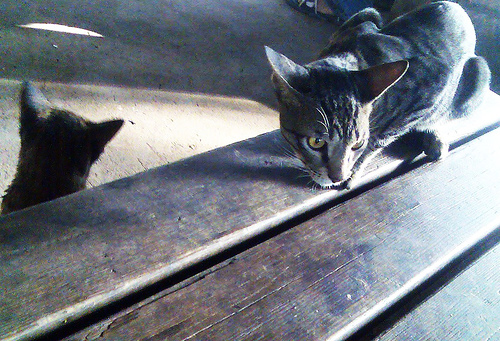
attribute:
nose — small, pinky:
[332, 160, 350, 184]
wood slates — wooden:
[0, 83, 499, 337]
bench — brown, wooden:
[0, 90, 499, 340]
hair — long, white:
[318, 122, 330, 132]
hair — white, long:
[316, 103, 328, 121]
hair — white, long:
[368, 120, 377, 129]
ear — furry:
[364, 53, 415, 114]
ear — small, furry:
[87, 115, 124, 153]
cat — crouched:
[257, 2, 492, 189]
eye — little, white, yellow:
[352, 136, 364, 153]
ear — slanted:
[356, 60, 411, 104]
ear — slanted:
[261, 45, 311, 97]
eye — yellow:
[308, 132, 325, 151]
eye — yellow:
[353, 136, 364, 149]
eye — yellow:
[308, 131, 330, 151]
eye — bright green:
[303, 132, 327, 153]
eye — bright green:
[349, 138, 366, 150]